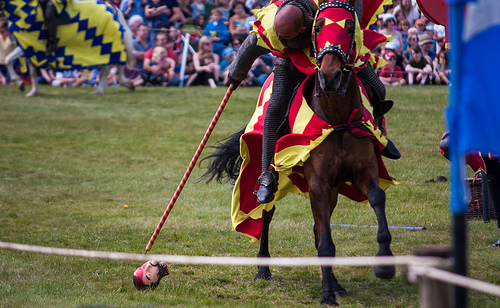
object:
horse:
[191, 0, 395, 307]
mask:
[310, 4, 357, 69]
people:
[0, 2, 451, 86]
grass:
[0, 83, 499, 306]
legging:
[257, 62, 387, 186]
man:
[228, 0, 401, 203]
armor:
[228, 1, 399, 203]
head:
[133, 259, 169, 291]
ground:
[1, 83, 499, 308]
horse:
[0, 1, 135, 97]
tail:
[192, 127, 246, 185]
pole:
[145, 83, 234, 251]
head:
[273, 5, 305, 40]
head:
[314, 0, 356, 95]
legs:
[307, 177, 337, 305]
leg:
[350, 176, 396, 279]